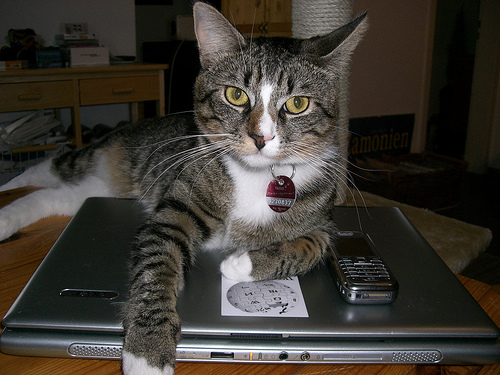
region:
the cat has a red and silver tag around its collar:
[266, 163, 300, 213]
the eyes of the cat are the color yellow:
[210, 82, 338, 123]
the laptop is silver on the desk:
[103, 187, 411, 349]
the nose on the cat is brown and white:
[251, 75, 274, 160]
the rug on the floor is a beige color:
[404, 202, 481, 276]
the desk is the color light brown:
[8, 62, 160, 119]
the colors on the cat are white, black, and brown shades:
[133, 157, 238, 349]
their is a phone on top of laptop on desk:
[323, 210, 393, 332]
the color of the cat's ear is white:
[190, 8, 234, 65]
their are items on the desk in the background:
[2, 14, 103, 67]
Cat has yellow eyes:
[210, 52, 355, 134]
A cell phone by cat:
[311, 200, 409, 333]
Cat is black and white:
[85, 9, 381, 328]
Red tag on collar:
[246, 167, 323, 215]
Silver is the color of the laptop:
[31, 144, 496, 374]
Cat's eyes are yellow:
[287, 83, 326, 123]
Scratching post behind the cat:
[282, 1, 390, 221]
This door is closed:
[431, 8, 483, 183]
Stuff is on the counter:
[5, 18, 175, 86]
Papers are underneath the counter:
[1, 107, 93, 189]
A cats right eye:
[223, 68, 256, 113]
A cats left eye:
[273, 93, 318, 123]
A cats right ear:
[183, 1, 258, 75]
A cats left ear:
[305, 4, 375, 71]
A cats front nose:
[244, 124, 274, 149]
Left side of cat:
[270, 16, 359, 290]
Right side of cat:
[177, 2, 262, 282]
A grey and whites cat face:
[219, 73, 315, 160]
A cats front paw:
[113, 292, 190, 373]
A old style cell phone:
[328, 228, 398, 315]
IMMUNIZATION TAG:
[262, 175, 307, 212]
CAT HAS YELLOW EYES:
[220, 81, 325, 118]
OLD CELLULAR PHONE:
[312, 210, 407, 311]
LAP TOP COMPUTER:
[30, 155, 496, 371]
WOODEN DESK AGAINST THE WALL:
[5, 27, 168, 140]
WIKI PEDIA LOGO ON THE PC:
[218, 271, 309, 324]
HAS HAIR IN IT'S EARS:
[326, 15, 371, 80]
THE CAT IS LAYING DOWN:
[41, 17, 421, 339]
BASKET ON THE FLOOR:
[362, 141, 473, 216]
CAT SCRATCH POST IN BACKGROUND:
[288, 4, 495, 279]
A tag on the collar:
[263, 166, 298, 217]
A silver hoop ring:
[267, 162, 298, 180]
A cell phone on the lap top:
[323, 220, 400, 304]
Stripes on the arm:
[275, 237, 330, 277]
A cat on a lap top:
[63, 5, 375, 363]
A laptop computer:
[201, 301, 498, 371]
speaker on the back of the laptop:
[386, 346, 443, 363]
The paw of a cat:
[214, 246, 266, 286]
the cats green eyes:
[212, 68, 324, 125]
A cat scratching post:
[288, 1, 354, 38]